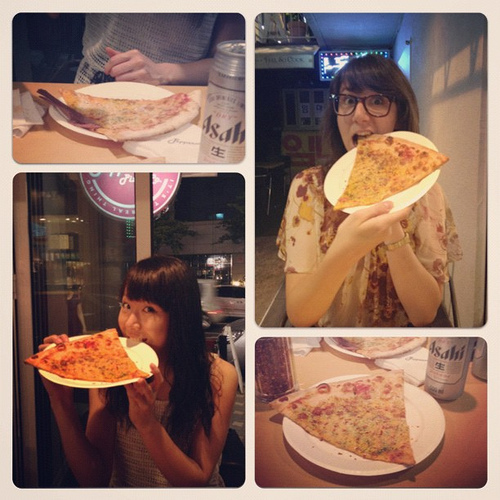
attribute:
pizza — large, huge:
[360, 145, 402, 187]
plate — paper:
[327, 165, 345, 189]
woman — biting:
[337, 91, 421, 320]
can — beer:
[427, 344, 482, 408]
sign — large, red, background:
[46, 149, 179, 225]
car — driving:
[204, 275, 238, 322]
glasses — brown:
[336, 90, 402, 122]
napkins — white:
[140, 145, 177, 166]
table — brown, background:
[29, 136, 75, 150]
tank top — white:
[127, 23, 180, 50]